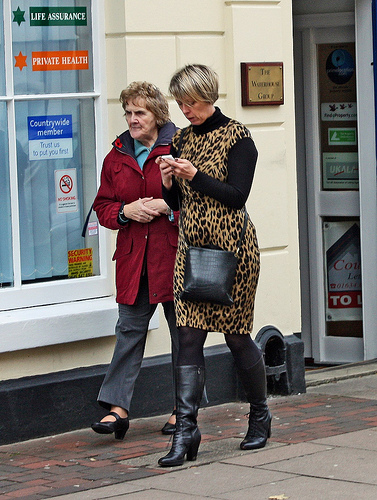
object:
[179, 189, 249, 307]
handbag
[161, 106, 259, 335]
dress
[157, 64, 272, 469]
woman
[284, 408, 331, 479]
sidewalk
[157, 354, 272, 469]
boots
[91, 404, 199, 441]
shoes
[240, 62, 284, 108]
plaque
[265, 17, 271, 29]
wall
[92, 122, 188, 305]
coat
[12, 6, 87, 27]
sticker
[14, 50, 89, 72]
sticker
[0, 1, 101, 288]
window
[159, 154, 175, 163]
cell phone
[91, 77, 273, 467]
women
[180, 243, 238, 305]
black purse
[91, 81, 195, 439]
lady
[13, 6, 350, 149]
building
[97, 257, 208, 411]
gray pants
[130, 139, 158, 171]
blue shirt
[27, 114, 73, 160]
sign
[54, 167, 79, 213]
sign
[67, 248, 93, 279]
sticker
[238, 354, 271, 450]
boot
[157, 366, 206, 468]
boot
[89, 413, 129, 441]
shoe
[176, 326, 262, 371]
black stockings